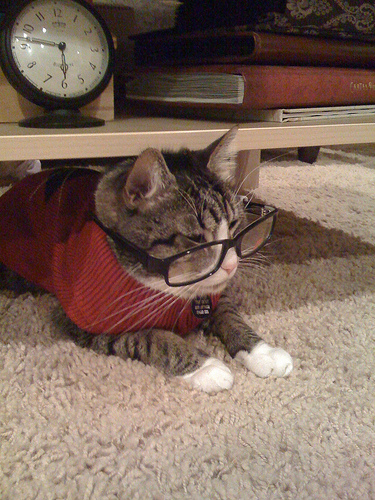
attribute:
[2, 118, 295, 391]
cat — laying, cute, wearing, white, gray, relaxing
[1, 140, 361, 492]
carpet — shaggy, gray, beige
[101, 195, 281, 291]
eye glass — black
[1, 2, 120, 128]
clock — white, black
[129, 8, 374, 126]
books — arranged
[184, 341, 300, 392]
claws — white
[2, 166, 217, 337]
dress — red, black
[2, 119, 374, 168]
table — long, wooden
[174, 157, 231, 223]
stripes — black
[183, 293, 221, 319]
tag — black